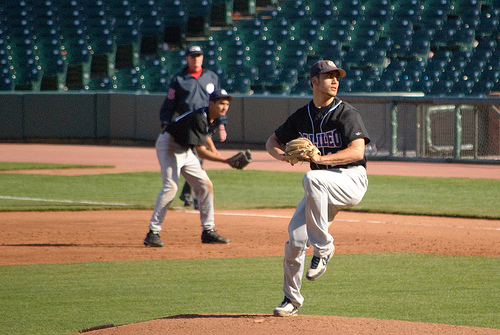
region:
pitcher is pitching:
[265, 59, 370, 316]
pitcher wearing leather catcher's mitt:
[282, 137, 319, 166]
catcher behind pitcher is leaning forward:
[139, 87, 253, 247]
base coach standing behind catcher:
[157, 43, 229, 210]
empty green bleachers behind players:
[0, 0, 498, 98]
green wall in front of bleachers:
[0, 91, 499, 151]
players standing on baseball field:
[0, 141, 499, 333]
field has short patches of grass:
[0, 162, 498, 334]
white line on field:
[0, 195, 499, 231]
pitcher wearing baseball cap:
[309, 58, 346, 78]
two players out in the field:
[109, 35, 398, 325]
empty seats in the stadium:
[29, 10, 499, 110]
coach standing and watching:
[138, 17, 258, 224]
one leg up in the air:
[294, 165, 391, 295]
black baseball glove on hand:
[223, 140, 258, 179]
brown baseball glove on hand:
[271, 125, 329, 175]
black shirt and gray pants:
[275, 91, 366, 310]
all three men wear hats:
[169, 33, 388, 136]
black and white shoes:
[266, 233, 362, 333]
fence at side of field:
[397, 96, 499, 178]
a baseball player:
[259, 60, 382, 319]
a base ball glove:
[285, 135, 320, 165]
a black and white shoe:
[302, 255, 333, 280]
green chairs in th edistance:
[375, 3, 490, 88]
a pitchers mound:
[128, 307, 463, 332]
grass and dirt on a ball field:
[2, 140, 123, 246]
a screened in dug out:
[407, 98, 494, 158]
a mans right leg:
[139, 176, 184, 248]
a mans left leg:
[302, 167, 363, 279]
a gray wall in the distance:
[8, 88, 120, 140]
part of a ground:
[137, 255, 184, 314]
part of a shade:
[230, 300, 250, 324]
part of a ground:
[386, 281, 412, 320]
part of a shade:
[225, 292, 248, 329]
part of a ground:
[406, 268, 435, 323]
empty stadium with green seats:
[0, 0, 498, 85]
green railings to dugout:
[378, 95, 488, 155]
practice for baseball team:
[125, 28, 403, 309]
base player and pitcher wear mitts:
[145, 60, 367, 315]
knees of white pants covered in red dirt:
[140, 150, 230, 255]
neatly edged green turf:
[0, 255, 497, 330]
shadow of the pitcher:
[75, 305, 285, 332]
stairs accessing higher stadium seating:
[7, 0, 287, 95]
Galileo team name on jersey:
[267, 116, 358, 156]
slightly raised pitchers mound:
[61, 301, 494, 330]